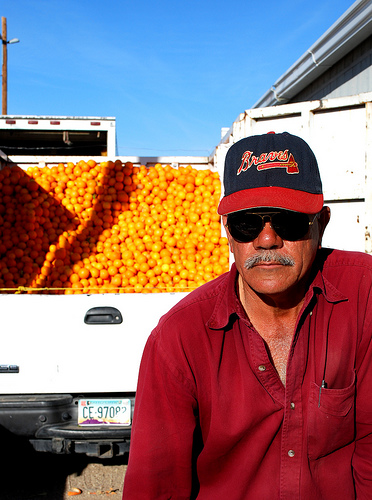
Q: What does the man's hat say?
A: Braves.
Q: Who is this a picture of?
A: A man.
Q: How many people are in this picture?
A: One.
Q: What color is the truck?
A: White.